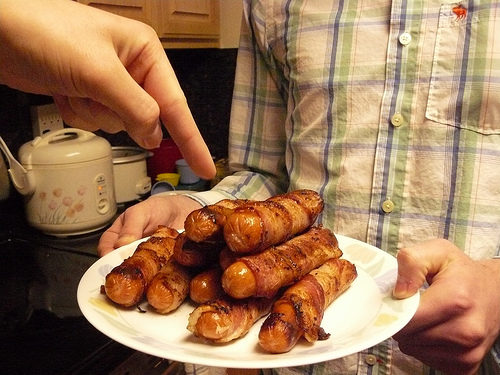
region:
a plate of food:
[24, 80, 458, 372]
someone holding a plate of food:
[43, 43, 470, 364]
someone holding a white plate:
[82, 131, 496, 353]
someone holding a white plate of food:
[41, 116, 482, 371]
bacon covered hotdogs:
[48, 99, 469, 371]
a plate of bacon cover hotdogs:
[74, 142, 461, 356]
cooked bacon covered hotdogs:
[37, 106, 454, 373]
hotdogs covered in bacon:
[109, 165, 436, 370]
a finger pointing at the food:
[28, 12, 415, 365]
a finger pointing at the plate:
[33, 9, 489, 366]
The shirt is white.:
[141, 0, 498, 374]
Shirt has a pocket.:
[131, 0, 498, 372]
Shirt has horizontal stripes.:
[154, 0, 496, 372]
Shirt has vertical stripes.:
[130, 1, 499, 373]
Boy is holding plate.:
[77, 1, 493, 372]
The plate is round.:
[70, 180, 425, 365]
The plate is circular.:
[56, 192, 421, 367]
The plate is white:
[76, 180, 422, 366]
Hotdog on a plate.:
[61, 169, 431, 372]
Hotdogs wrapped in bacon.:
[74, 180, 426, 373]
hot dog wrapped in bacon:
[212, 186, 339, 257]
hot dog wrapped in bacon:
[209, 219, 347, 304]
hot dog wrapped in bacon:
[248, 251, 361, 364]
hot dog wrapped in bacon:
[182, 286, 267, 350]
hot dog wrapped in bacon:
[174, 191, 254, 243]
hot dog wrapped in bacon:
[96, 213, 186, 314]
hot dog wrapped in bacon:
[166, 227, 213, 270]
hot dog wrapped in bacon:
[139, 250, 200, 316]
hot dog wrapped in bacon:
[180, 262, 231, 309]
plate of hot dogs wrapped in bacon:
[68, 163, 434, 372]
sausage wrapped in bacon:
[86, 180, 338, 355]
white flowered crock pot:
[9, 121, 140, 240]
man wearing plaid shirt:
[173, 0, 499, 373]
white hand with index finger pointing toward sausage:
[3, 0, 235, 197]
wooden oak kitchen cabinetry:
[95, 3, 224, 48]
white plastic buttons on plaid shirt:
[370, 22, 426, 238]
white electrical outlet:
[31, 97, 69, 150]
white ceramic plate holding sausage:
[75, 213, 422, 362]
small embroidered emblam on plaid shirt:
[446, 0, 470, 27]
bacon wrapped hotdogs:
[145, 204, 340, 348]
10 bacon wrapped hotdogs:
[127, 201, 354, 370]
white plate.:
[88, 218, 439, 354]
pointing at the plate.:
[90, 52, 252, 184]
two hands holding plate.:
[120, 160, 491, 346]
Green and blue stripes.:
[325, 50, 352, 108]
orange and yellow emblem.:
[449, 5, 471, 27]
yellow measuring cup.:
[155, 168, 180, 188]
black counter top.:
[17, 271, 79, 349]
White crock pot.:
[112, 143, 158, 196]